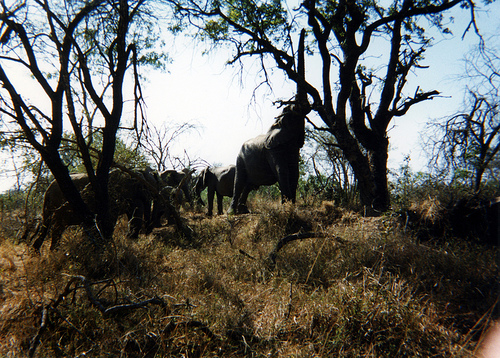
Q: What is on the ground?
A: Yellow grass.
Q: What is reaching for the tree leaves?
A: The elephant.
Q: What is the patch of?
A: Thick tall grass.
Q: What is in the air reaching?
A: Trunk.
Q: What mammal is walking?
A: Elephants.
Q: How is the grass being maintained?
A: Dried out.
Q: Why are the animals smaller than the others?
A: Babies.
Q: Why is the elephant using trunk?
A: Eating.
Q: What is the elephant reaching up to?
A: Tree.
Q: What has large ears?
A: Elephants.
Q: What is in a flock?
A: Elephants.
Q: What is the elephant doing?
A: Reaching for leaves.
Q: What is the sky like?
A: Clear.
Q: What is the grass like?
A: Dead.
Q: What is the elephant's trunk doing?
A: Stretching.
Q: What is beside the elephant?
A: Baby elephant.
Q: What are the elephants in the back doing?
A: Grazing.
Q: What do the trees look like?
A: Sparse.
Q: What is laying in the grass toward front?
A: Sticks.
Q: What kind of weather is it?
A: Sunny.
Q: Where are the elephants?
A: In woods.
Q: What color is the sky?
A: Blue.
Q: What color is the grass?
A: Yellow.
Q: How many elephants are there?
A: Four.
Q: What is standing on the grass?
A: Elephants.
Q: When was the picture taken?
A: Daytime.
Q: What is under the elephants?
A: Grass.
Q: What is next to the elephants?
A: Trees.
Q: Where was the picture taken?
A: The jungle.